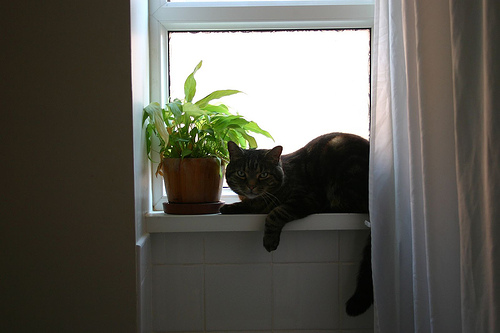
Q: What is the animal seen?
A: Cat.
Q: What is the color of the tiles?
A: White.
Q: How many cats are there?
A: One.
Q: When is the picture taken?
A: Daytime.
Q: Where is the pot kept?
A: Window.